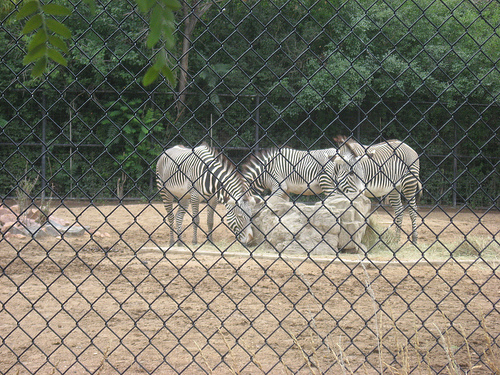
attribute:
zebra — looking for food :
[106, 105, 325, 297]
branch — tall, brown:
[171, 3, 204, 122]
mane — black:
[335, 132, 370, 156]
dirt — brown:
[76, 298, 296, 353]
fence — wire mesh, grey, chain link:
[7, 1, 499, 372]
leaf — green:
[12, 10, 39, 22]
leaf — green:
[42, 3, 69, 19]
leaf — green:
[142, 63, 158, 88]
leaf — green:
[158, 23, 176, 49]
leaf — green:
[47, 49, 67, 66]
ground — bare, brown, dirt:
[1, 209, 495, 374]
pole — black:
[14, 106, 57, 192]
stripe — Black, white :
[284, 147, 286, 177]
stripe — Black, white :
[291, 147, 295, 179]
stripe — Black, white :
[296, 151, 299, 179]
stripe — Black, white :
[305, 146, 312, 183]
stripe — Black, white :
[307, 154, 315, 180]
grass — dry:
[403, 242, 445, 254]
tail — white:
[416, 170, 425, 201]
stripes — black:
[391, 142, 403, 182]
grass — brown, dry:
[260, 274, 379, 332]